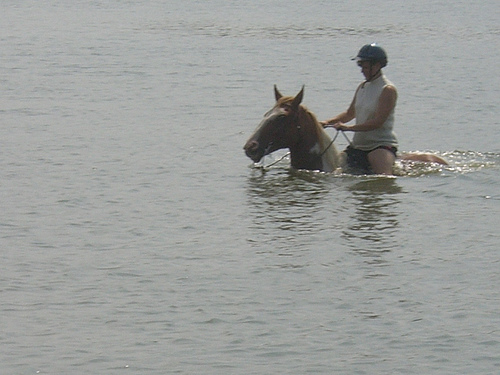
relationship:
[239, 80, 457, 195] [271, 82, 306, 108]
horse has ears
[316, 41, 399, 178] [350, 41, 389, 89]
human has helmet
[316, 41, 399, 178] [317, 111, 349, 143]
human holds reins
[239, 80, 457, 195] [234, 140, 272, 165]
horse has nose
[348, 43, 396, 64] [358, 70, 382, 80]
cap has chin strap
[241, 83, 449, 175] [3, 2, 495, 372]
horse in water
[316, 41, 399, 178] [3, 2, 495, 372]
human in water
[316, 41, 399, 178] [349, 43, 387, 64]
human wears helmet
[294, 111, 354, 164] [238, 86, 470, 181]
halter on horse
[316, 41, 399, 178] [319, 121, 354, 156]
human holds halter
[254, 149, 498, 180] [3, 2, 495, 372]
ripples in water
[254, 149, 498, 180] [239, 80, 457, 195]
ripples caused by horse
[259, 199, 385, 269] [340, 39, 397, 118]
water surrounds rider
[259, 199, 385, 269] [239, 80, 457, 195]
water surrounds horse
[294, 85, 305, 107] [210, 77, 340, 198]
ear of horse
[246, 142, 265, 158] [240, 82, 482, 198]
mouth of horse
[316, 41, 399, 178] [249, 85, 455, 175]
human on horse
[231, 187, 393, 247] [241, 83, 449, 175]
water next to horse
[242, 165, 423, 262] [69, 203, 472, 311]
reflection in water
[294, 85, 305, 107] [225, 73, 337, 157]
ear of horse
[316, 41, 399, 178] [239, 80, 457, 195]
human riding horse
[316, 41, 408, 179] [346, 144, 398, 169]
human wears pant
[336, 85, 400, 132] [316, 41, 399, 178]
arm on human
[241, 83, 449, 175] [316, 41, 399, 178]
horse with human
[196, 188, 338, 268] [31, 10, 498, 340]
ripple in water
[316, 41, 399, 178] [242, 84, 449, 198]
human on horse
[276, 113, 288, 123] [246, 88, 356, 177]
eye on horse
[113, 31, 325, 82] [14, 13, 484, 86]
water in background